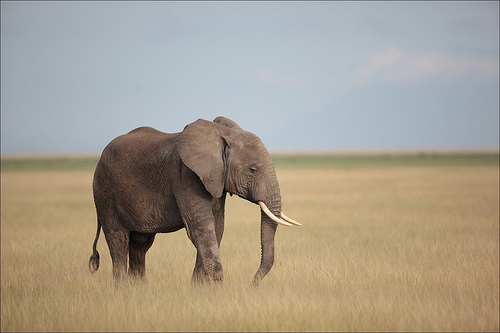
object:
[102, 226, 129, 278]
back leg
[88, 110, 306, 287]
elephant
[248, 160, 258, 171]
right eye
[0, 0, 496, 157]
cloud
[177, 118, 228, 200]
ear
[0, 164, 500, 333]
grass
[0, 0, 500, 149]
sky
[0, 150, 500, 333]
ground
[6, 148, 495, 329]
field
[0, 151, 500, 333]
plain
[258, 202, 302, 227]
tusks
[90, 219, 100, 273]
tail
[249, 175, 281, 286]
trunk